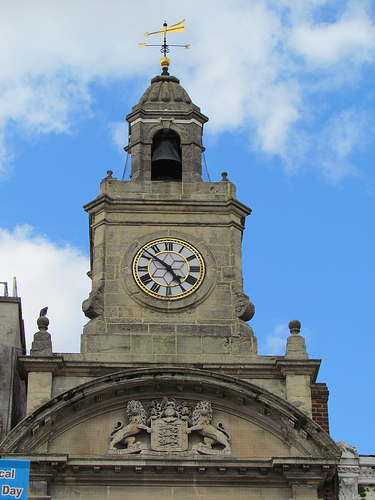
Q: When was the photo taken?
A: 4:52.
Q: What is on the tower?
A: Clock.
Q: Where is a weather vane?
A: On building.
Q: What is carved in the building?
A: Lions.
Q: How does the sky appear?
A: Cloudy.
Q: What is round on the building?
A: Clock.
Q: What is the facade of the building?
A: Stones.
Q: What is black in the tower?
A: Bell.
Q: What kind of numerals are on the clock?
A: Roman.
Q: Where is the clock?
A: On the tower.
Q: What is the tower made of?
A: Stone.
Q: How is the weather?
A: Partially cloudy.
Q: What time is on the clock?
A: 5:52.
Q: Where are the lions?
A: Below the clock.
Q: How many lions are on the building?
A: Two.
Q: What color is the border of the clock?
A: Gold.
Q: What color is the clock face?
A: White.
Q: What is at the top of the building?
A: A bell.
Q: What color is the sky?
A: Blue.